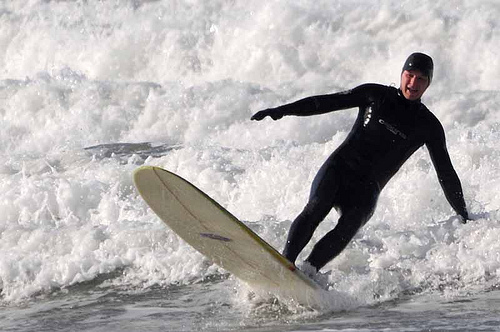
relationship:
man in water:
[250, 47, 472, 284] [9, 255, 181, 318]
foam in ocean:
[31, 62, 456, 239] [38, 226, 493, 323]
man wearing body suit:
[250, 47, 472, 284] [239, 84, 471, 267]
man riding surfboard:
[250, 47, 472, 284] [124, 167, 332, 305]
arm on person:
[250, 84, 365, 124] [224, 48, 477, 281]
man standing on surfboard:
[250, 47, 472, 284] [127, 157, 322, 311]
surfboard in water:
[124, 159, 337, 312] [22, 288, 204, 330]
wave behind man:
[7, 7, 137, 285] [250, 47, 472, 284]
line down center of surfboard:
[153, 165, 279, 296] [124, 167, 332, 305]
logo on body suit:
[377, 108, 412, 143] [239, 79, 476, 264]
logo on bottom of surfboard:
[192, 228, 240, 248] [123, 152, 347, 309]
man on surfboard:
[250, 47, 472, 284] [124, 167, 332, 305]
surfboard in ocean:
[124, 159, 337, 312] [4, 8, 496, 305]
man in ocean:
[250, 47, 472, 284] [0, 1, 497, 329]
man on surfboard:
[250, 47, 472, 284] [124, 159, 337, 312]